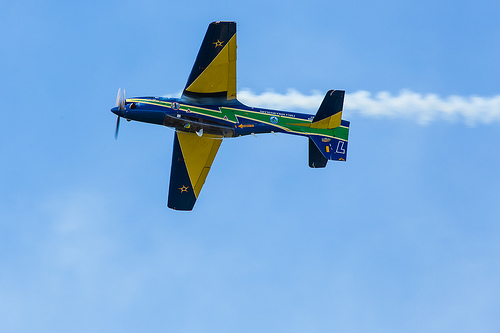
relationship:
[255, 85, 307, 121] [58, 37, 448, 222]
number on plane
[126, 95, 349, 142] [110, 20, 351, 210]
stripe on airplane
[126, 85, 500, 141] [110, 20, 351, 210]
stripe on airplane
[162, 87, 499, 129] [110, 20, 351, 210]
contrail from airplane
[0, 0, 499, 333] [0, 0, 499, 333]
cloud in cloud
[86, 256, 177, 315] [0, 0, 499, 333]
cloud in cloud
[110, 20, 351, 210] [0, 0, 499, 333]
airplane in cloud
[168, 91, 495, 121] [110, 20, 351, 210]
contrail off airplane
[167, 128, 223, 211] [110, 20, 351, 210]
wing on airplane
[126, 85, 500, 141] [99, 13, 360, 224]
stripe on plane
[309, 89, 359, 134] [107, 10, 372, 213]
tail on plane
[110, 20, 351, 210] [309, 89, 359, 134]
airplane on tail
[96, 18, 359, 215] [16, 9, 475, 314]
airplane in sky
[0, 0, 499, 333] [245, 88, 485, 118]
cloud of smoke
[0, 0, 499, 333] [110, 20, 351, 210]
cloud behind airplane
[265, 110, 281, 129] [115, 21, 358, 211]
logo on airplane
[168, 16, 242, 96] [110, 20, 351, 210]
wing on airplane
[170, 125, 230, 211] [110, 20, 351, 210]
wing on airplane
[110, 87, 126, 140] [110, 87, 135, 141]
fan on nose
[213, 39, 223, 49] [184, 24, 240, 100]
star on wing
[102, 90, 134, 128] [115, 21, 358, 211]
nose of airplane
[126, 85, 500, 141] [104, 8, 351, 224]
stripe on airplane